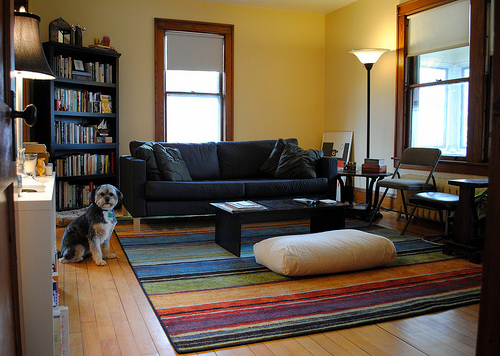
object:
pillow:
[247, 224, 401, 280]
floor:
[56, 206, 485, 355]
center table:
[206, 201, 354, 260]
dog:
[56, 183, 128, 268]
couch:
[113, 138, 341, 224]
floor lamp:
[345, 48, 389, 222]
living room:
[0, 0, 498, 353]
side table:
[337, 169, 394, 220]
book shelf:
[30, 42, 120, 213]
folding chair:
[366, 147, 443, 237]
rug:
[114, 217, 483, 352]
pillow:
[153, 144, 192, 181]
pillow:
[132, 143, 159, 181]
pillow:
[274, 144, 322, 179]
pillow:
[259, 138, 284, 175]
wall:
[119, 4, 326, 139]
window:
[395, 2, 489, 175]